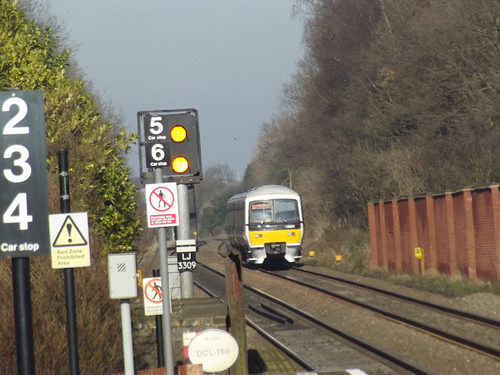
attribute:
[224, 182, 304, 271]
train — white, yellow, silver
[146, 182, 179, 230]
sign — warning, white, red, black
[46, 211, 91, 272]
sign — yellow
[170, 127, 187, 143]
light — yellow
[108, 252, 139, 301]
box — silver, gray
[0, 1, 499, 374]
trees — green, large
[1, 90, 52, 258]
sign — black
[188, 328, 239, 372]
sign — circular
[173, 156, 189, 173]
light — yellow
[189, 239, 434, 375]
track — empty